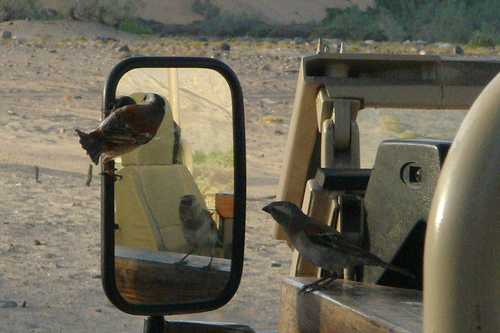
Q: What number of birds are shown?
A: Two.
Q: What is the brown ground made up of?
A: Dirt.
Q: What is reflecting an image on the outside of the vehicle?
A: Mirro.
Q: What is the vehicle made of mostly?
A: Metal.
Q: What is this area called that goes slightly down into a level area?
A: Slope.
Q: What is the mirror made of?
A: Glass.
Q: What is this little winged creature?
A: Bird.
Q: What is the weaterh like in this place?
A: Sunny.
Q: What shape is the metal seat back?
A: Curved.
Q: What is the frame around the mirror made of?
A: Plastic.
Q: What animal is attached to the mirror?
A: A bird.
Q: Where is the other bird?
A: The window ledge of th jeep.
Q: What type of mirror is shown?
A: Rear view mirror.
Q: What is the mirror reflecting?
A: The car.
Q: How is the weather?
A: Clear and sunny.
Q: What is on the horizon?
A: Rocks.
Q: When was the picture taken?
A: Afternoon.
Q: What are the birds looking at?
A: The mirror.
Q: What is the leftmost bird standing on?
A: The side of the mirror.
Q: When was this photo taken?
A: During the day.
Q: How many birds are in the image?
A: 2.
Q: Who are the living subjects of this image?
A: The birds.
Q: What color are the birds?
A: Brown and white.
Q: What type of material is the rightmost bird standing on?
A: Metal.